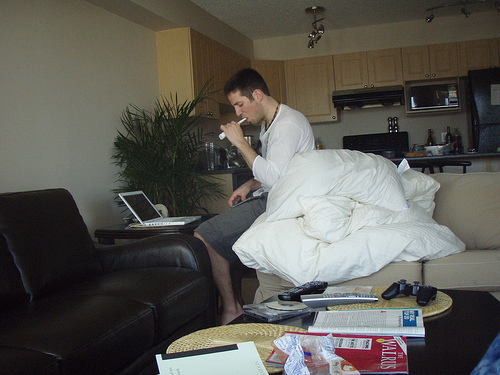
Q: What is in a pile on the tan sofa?
A: White linens.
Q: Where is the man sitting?
A: On the arm of the sofa.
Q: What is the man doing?
A: Brushing his teeth.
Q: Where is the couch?
A: Against the wall.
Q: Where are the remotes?
A: On the coffee table.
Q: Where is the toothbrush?
A: In the man's hands.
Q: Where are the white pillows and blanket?
A: On cream colored couch.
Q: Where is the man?
A: Sitting in front of the computer.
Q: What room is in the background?
A: Kitchen.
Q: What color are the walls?
A: White.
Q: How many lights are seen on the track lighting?
A: 2.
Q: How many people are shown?
A: 1.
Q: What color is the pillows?
A: White.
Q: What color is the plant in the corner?
A: Green.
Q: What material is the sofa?
A: Black leather.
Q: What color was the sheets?
A: White.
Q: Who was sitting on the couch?
A: A man.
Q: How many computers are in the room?
A: One.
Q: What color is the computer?
A: White.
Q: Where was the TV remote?
A: On the table.